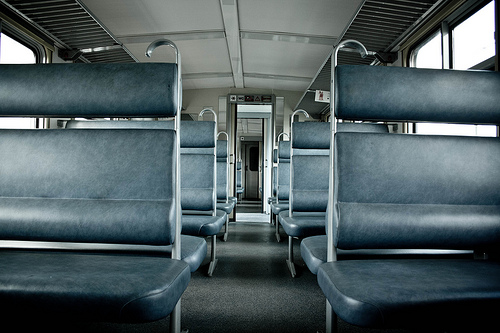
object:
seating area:
[272, 35, 497, 319]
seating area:
[0, 37, 244, 322]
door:
[227, 103, 271, 221]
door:
[242, 141, 260, 199]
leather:
[338, 137, 493, 239]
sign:
[318, 89, 329, 100]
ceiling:
[2, 0, 498, 110]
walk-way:
[183, 198, 320, 331]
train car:
[1, 0, 498, 331]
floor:
[163, 201, 325, 331]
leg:
[284, 234, 302, 279]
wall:
[107, 84, 377, 205]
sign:
[229, 93, 273, 101]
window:
[0, 26, 48, 132]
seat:
[0, 235, 212, 269]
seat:
[298, 227, 499, 270]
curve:
[325, 39, 341, 331]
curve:
[167, 37, 185, 331]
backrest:
[3, 127, 172, 247]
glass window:
[404, 8, 500, 133]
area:
[6, 141, 498, 312]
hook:
[146, 37, 183, 66]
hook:
[331, 36, 368, 63]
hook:
[198, 105, 221, 121]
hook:
[289, 107, 310, 123]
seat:
[275, 123, 331, 252]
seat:
[178, 122, 221, 272]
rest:
[2, 63, 180, 114]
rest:
[340, 66, 495, 122]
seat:
[4, 37, 184, 333]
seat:
[322, 37, 493, 328]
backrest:
[338, 128, 496, 249]